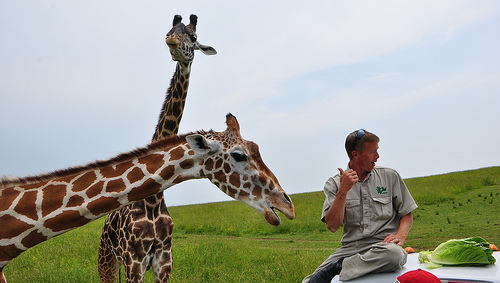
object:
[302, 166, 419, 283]
uniform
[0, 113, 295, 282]
giraffe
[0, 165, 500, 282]
grass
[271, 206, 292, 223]
mouth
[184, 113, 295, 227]
head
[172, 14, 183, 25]
horn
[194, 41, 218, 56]
ear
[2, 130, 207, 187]
hair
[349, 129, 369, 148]
glasses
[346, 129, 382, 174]
head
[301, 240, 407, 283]
pants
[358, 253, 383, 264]
wrinkle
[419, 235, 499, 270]
food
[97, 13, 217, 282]
giraffe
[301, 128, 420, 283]
guy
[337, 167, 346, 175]
thumb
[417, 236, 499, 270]
leaves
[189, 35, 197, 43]
eye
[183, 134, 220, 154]
ear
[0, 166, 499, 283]
hill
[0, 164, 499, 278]
field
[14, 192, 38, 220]
spot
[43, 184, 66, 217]
spot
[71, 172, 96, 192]
spot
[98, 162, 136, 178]
spot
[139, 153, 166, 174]
spot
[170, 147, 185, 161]
spot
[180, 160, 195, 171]
spot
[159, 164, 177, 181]
spot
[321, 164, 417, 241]
shirt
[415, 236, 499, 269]
lettuce piece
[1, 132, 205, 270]
neck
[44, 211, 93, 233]
spot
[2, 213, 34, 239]
spot